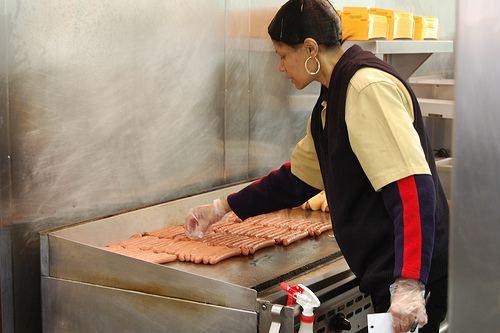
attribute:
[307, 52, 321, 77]
earrings — large, hoop, gold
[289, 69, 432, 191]
t-shirt — yellow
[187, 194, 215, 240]
gloves — plastic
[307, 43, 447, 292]
vest — brown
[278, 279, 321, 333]
spray bottle — white, red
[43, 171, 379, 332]
grill — silver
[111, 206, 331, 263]
hotdogs — red hots, orange, cooking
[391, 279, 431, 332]
glove — the left, clear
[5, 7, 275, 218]
wall — stainless steel, metal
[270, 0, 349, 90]
head — covered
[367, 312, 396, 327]
paper — white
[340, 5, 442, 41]
containers — yellow